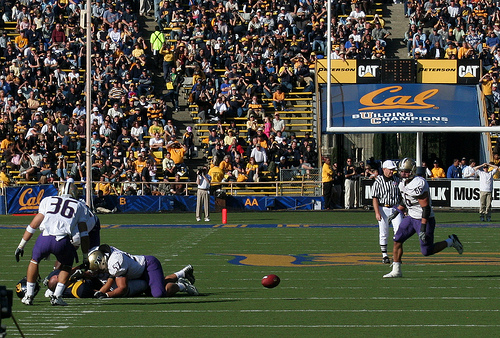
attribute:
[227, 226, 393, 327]
field — green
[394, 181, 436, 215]
shrit — white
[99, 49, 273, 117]
people — sitting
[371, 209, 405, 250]
plants — tan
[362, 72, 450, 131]
sign — yellow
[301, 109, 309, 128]
seats — yellow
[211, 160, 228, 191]
shirt — yellow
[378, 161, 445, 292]
player — getting, tackling, play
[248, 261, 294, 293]
football — brown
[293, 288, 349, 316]
lines — white, painted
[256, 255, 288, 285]
ball — foot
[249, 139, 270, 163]
man — watching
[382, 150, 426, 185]
helmet — football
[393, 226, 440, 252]
pants — blue, white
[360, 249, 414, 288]
shoes — white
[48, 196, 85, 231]
jersety — white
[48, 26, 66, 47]
shirts — red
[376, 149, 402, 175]
cap — white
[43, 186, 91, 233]
jersey — white, team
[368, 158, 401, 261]
referee — black, white